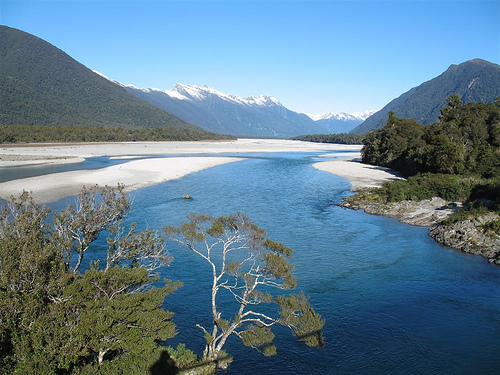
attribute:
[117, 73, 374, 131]
peaks — mountain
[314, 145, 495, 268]
line — shore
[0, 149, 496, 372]
water — blue , bright blue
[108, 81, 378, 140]
mountain — snow covered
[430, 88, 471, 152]
tree — green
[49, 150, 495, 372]
river — sandy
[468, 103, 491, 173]
tree — green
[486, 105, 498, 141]
tree — green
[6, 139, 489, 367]
river — sandy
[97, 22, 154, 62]
clouds — white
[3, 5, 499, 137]
sky — blue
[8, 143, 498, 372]
lake — calm, blue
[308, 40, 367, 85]
clouds — white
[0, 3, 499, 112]
sky — blue